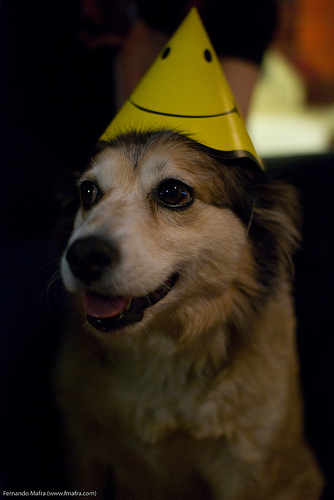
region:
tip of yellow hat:
[184, 1, 204, 15]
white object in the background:
[252, 52, 310, 118]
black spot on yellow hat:
[201, 46, 216, 61]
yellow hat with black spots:
[113, 4, 275, 167]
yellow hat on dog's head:
[64, 8, 302, 230]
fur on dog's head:
[109, 127, 189, 165]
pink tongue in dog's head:
[62, 288, 142, 319]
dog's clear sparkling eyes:
[144, 169, 207, 214]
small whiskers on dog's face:
[112, 265, 195, 317]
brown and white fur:
[158, 360, 297, 445]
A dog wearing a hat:
[48, 1, 294, 336]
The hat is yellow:
[92, 2, 265, 163]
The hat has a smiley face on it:
[103, 3, 268, 167]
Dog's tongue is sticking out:
[76, 277, 194, 336]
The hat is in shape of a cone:
[95, 0, 271, 173]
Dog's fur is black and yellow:
[204, 151, 305, 275]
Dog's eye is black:
[151, 171, 202, 213]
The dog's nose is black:
[64, 235, 121, 280]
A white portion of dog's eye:
[91, 180, 98, 202]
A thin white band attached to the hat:
[241, 162, 268, 246]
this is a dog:
[60, 152, 300, 482]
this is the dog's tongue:
[85, 292, 121, 313]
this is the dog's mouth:
[67, 272, 182, 334]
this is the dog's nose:
[63, 239, 126, 282]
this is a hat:
[89, 2, 264, 164]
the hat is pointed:
[173, 7, 202, 34]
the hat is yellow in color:
[162, 69, 222, 101]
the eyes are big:
[71, 176, 204, 215]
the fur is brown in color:
[168, 403, 280, 444]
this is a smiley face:
[124, 40, 243, 120]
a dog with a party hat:
[33, 4, 327, 498]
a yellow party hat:
[85, 4, 273, 159]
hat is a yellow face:
[86, 4, 267, 165]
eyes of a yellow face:
[142, 35, 228, 76]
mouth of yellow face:
[121, 88, 245, 124]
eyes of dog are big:
[62, 166, 201, 211]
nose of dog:
[53, 227, 124, 284]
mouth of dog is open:
[48, 269, 182, 342]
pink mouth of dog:
[69, 290, 137, 331]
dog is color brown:
[45, 127, 332, 496]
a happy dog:
[27, 8, 333, 496]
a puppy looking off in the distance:
[2, 5, 331, 498]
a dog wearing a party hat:
[2, 1, 325, 498]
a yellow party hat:
[91, 1, 283, 176]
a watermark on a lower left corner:
[2, 482, 109, 498]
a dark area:
[2, 5, 333, 495]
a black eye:
[145, 167, 200, 223]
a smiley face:
[92, 7, 272, 175]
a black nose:
[57, 224, 128, 317]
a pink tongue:
[67, 270, 154, 336]